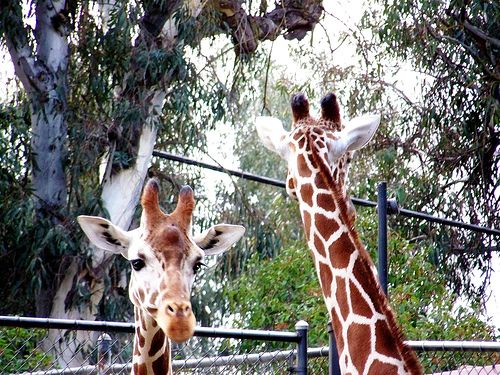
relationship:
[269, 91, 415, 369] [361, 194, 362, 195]
giraffe has head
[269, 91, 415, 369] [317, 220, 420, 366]
giraffe has neck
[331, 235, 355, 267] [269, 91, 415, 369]
spot on giraffe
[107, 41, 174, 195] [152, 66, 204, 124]
trunk with leaves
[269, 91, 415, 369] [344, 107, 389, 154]
giraffe has ear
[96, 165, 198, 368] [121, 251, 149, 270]
giraffe has eye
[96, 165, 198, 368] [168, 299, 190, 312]
giraffe has nose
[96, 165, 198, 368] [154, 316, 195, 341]
giraffe has mouth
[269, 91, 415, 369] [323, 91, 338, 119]
giraffe has horn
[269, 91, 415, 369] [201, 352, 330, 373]
giraffe by fencing